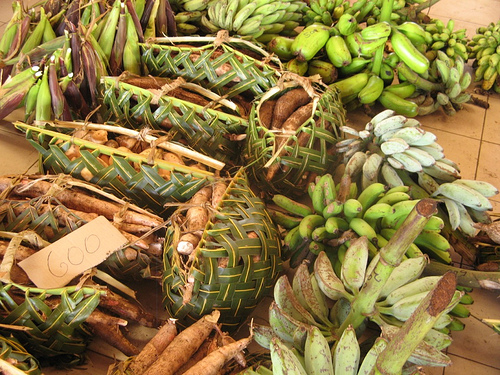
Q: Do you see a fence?
A: No, there are no fences.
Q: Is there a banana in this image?
A: Yes, there is a banana.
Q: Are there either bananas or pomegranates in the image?
A: Yes, there is a banana.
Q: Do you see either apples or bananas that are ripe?
A: Yes, the banana is ripe.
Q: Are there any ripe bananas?
A: Yes, there is a ripe banana.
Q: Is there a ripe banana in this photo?
A: Yes, there is a ripe banana.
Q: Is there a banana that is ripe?
A: Yes, there is a banana that is ripe.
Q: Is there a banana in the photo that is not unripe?
A: Yes, there is an ripe banana.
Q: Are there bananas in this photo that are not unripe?
A: Yes, there is an ripe banana.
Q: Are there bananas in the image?
A: Yes, there is a banana.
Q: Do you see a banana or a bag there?
A: Yes, there is a banana.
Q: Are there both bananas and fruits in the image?
A: Yes, there are both a banana and a fruit.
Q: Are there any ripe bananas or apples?
A: Yes, there is a ripe banana.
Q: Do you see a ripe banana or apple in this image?
A: Yes, there is a ripe banana.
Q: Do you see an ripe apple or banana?
A: Yes, there is a ripe banana.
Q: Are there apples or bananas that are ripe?
A: Yes, the banana is ripe.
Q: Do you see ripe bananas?
A: Yes, there is a ripe banana.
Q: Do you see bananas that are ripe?
A: Yes, there is a banana that is ripe.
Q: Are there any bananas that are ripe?
A: Yes, there is a banana that is ripe.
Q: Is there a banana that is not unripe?
A: Yes, there is an ripe banana.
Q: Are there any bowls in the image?
A: No, there are no bowls.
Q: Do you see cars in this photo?
A: No, there are no cars.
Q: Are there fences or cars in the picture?
A: No, there are no cars or fences.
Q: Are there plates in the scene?
A: No, there are no plates.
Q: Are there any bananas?
A: Yes, there is a banana.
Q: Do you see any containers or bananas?
A: Yes, there is a banana.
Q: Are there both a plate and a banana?
A: No, there is a banana but no plates.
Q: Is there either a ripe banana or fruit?
A: Yes, there is a ripe banana.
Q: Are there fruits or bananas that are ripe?
A: Yes, the banana is ripe.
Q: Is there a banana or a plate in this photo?
A: Yes, there is a banana.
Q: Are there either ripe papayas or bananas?
A: Yes, there is a ripe banana.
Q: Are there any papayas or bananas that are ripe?
A: Yes, the banana is ripe.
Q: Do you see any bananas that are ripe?
A: Yes, there is a ripe banana.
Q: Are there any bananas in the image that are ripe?
A: Yes, there is a banana that is ripe.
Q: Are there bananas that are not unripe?
A: Yes, there is an ripe banana.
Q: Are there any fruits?
A: Yes, there is a fruit.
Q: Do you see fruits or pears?
A: Yes, there is a fruit.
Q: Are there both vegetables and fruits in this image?
A: Yes, there are both a fruit and vegetables.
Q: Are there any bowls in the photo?
A: No, there are no bowls.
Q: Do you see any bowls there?
A: No, there are no bowls.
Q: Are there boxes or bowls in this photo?
A: No, there are no bowls or boxes.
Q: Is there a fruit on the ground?
A: Yes, there is a fruit on the ground.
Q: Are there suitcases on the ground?
A: No, there is a fruit on the ground.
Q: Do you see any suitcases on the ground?
A: No, there is a fruit on the ground.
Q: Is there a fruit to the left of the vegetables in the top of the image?
A: Yes, there is a fruit to the left of the vegetables.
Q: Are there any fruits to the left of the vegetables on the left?
A: Yes, there is a fruit to the left of the vegetables.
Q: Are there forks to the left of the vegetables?
A: No, there is a fruit to the left of the vegetables.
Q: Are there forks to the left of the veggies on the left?
A: No, there is a fruit to the left of the vegetables.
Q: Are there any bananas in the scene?
A: Yes, there is a banana.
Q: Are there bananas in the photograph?
A: Yes, there is a banana.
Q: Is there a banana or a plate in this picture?
A: Yes, there is a banana.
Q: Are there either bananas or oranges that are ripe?
A: Yes, the banana is ripe.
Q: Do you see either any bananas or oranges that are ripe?
A: Yes, the banana is ripe.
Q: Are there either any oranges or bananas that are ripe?
A: Yes, the banana is ripe.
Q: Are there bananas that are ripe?
A: Yes, there is a banana that is ripe.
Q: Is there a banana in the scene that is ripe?
A: Yes, there is a banana that is ripe.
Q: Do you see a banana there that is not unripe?
A: Yes, there is an ripe banana.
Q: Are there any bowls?
A: No, there are no bowls.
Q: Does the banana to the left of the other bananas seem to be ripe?
A: Yes, the banana is ripe.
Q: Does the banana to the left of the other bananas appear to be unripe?
A: No, the banana is ripe.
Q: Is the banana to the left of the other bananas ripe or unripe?
A: The banana is ripe.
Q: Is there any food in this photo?
A: Yes, there is food.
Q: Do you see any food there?
A: Yes, there is food.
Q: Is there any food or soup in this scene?
A: Yes, there is food.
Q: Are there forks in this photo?
A: No, there are no forks.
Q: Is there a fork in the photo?
A: No, there are no forks.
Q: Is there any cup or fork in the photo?
A: No, there are no forks or cups.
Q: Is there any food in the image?
A: Yes, there is food.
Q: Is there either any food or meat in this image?
A: Yes, there is food.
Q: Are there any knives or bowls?
A: No, there are no bowls or knives.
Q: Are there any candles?
A: No, there are no candles.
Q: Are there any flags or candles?
A: No, there are no candles or flags.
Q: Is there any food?
A: Yes, there is food.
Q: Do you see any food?
A: Yes, there is food.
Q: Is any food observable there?
A: Yes, there is food.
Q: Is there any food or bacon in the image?
A: Yes, there is food.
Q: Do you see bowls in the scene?
A: No, there are no bowls.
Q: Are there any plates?
A: No, there are no plates.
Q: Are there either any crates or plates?
A: No, there are no plates or crates.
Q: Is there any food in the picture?
A: Yes, there is food.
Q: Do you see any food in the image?
A: Yes, there is food.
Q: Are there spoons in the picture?
A: No, there are no spoons.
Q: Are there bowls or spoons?
A: No, there are no spoons or bowls.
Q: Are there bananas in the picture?
A: Yes, there are bananas.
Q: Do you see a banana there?
A: Yes, there are bananas.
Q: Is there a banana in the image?
A: Yes, there are bananas.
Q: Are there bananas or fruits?
A: Yes, there are bananas.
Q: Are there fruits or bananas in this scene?
A: Yes, there are bananas.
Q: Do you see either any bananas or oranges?
A: Yes, there are bananas.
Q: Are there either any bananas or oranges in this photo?
A: Yes, there are bananas.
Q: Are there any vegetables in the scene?
A: Yes, there are vegetables.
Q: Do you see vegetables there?
A: Yes, there are vegetables.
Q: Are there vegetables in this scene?
A: Yes, there are vegetables.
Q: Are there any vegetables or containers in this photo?
A: Yes, there are vegetables.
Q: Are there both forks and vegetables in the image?
A: No, there are vegetables but no forks.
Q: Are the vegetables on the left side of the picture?
A: Yes, the vegetables are on the left of the image.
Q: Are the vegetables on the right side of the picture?
A: No, the vegetables are on the left of the image.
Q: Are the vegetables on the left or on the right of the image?
A: The vegetables are on the left of the image.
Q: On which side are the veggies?
A: The veggies are on the left of the image.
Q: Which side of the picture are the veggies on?
A: The veggies are on the left of the image.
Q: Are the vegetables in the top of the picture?
A: Yes, the vegetables are in the top of the image.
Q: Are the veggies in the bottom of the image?
A: No, the veggies are in the top of the image.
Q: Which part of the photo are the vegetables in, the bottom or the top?
A: The vegetables are in the top of the image.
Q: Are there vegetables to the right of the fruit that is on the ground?
A: Yes, there are vegetables to the right of the fruit.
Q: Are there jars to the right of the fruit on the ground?
A: No, there are vegetables to the right of the fruit.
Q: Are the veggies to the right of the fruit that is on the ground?
A: Yes, the veggies are to the right of the fruit.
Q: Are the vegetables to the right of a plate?
A: No, the vegetables are to the right of the fruit.